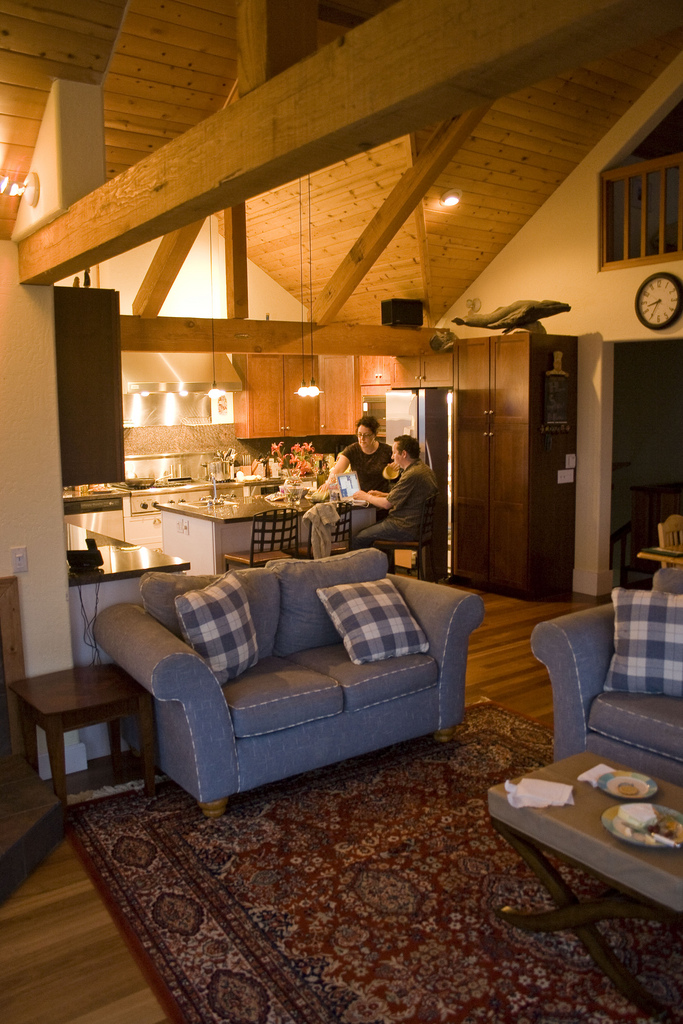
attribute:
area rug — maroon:
[60, 699, 598, 1018]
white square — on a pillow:
[343, 593, 367, 616]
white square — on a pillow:
[344, 593, 368, 612]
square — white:
[223, 602, 275, 636]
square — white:
[201, 577, 228, 604]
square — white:
[218, 569, 242, 596]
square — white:
[181, 587, 208, 611]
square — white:
[330, 592, 359, 624]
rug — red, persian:
[133, 781, 611, 1019]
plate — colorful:
[581, 755, 681, 859]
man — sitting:
[340, 424, 480, 558]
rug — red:
[132, 738, 595, 1017]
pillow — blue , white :
[322, 569, 431, 693]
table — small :
[40, 609, 216, 875]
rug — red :
[164, 712, 584, 1008]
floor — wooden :
[19, 838, 132, 1006]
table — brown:
[468, 709, 617, 984]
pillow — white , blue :
[165, 553, 276, 703]